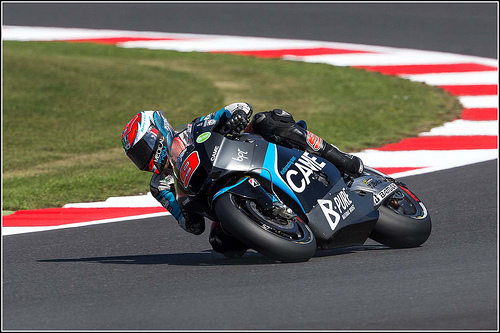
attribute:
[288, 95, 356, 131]
grass — green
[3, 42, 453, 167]
grass — green 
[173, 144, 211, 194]
numbernine — red 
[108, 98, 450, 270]
racing motorcycle — black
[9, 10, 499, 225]
curve — white 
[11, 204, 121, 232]
paint — pink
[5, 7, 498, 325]
race track — black , paved 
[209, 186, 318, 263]
front wheel — black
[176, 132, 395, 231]
frame — blue 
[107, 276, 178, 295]
track —  freshly painted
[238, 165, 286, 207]
cord — blue 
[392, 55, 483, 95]
line — red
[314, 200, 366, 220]
writing — white 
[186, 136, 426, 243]
motorcycle — speeding 